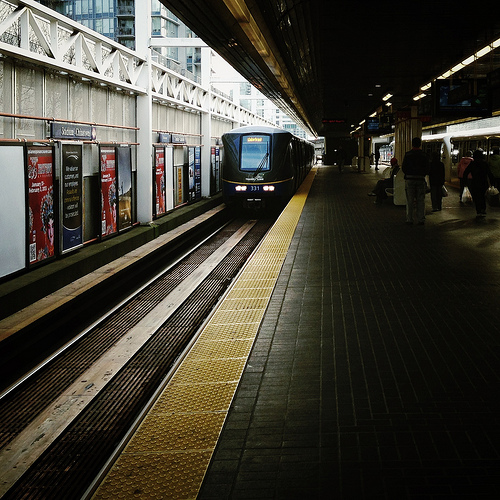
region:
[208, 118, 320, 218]
train at a train station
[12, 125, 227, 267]
advertisements on a wall at a station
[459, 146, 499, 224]
person in black carrying two bags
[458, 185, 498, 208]
two clear plastic bags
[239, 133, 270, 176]
front window on a train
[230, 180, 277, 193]
headlights on the front of a train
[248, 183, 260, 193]
number 331 on a train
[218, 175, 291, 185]
yellow stripe on a train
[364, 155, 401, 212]
person sitting on a bench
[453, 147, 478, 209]
person wearing a pink jacket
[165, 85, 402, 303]
Train pulling into station.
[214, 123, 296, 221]
Four round lights number 331.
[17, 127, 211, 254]
Panels provide advertising space.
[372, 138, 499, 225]
Passengers wait station platform.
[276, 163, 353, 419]
Station cement platform parallel tracks.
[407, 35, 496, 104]
Overhead lighting train station.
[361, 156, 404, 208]
Waiting passenger sitting bench.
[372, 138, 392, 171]
Person far distance vending machines.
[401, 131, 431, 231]
Man tan pants looking toward entrance.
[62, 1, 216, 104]
Hi-rise building outside train station.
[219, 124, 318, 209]
a black commuter passenger train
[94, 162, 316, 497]
a long yellow line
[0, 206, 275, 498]
a set of train tracks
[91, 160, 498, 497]
a passenger boarding platform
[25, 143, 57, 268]
a promotional banner advertisement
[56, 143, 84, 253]
a promotional banner advertisement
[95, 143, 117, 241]
a promotional banner advertisement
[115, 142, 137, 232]
a promotional banner advertisement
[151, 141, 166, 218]
a promotional banner advertisement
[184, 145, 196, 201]
a promotional banner advertisement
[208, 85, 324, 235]
Train on the tracks.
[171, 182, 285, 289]
Tracks with a train on it.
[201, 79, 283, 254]
Windows on the train.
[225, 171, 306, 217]
Lights on the train.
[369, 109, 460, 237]
People on the side walk.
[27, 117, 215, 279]
Coke machines in the background.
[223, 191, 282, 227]
Wheels on the train.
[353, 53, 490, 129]
Lights on the ceiling.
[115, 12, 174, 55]
Windows on the building.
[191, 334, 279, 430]
Yellow part of the sidewalk.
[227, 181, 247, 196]
The left headlights on the train.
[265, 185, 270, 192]
The right headlights on the train.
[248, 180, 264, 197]
The white numbers in between the headlights on the train.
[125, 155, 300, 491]
The yellow area on the platform.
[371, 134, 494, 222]
The people standing on the platform.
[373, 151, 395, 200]
The person sitting on a bench on the platform.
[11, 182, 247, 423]
The track area where the train is driving.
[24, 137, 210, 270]
The posters on the wall to the left of the train.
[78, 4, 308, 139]
The buildings on the left.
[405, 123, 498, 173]
The train on the right side.